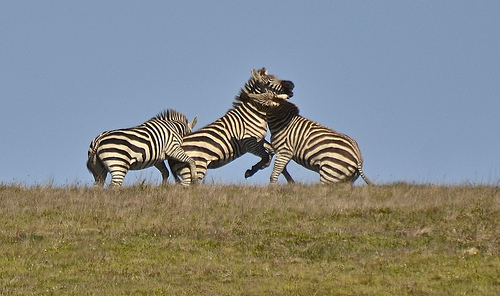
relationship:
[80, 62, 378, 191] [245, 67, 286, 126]
zebras have heads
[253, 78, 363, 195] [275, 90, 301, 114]
zebra has mane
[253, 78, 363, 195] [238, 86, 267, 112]
zebra has snout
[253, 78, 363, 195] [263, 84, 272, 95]
zebra has ear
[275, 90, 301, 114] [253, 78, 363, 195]
mane on a zebra